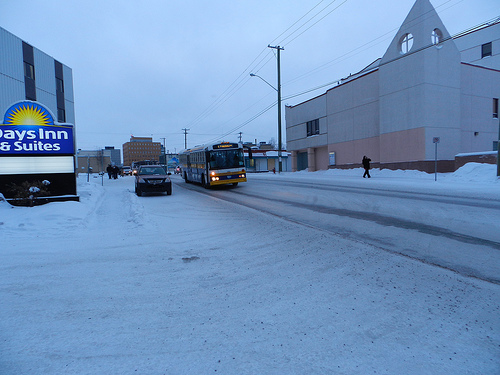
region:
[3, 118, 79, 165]
blue and yellow sign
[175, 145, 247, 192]
yellow school bus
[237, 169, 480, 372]
road is white and snow covered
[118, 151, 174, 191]
SUV next to school bus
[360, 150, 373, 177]
person is walking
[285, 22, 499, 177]
large white building near school bus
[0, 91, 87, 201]
hotel on side of road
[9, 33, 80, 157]
white hotel next to bus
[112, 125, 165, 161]
orange building in background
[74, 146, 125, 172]
tan building next to orange building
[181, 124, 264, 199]
a bus driving down a street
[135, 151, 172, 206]
a vehicle pulled off to the side of a road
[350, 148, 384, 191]
a person walking in the snow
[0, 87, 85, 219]
a hotel sign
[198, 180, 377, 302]
the road way covered in snow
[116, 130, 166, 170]
a red building with several levels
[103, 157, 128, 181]
people walking in the snow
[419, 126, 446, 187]
a metal road sign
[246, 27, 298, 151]
a wooden electrical pole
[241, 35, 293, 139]
a street lamp attached to a pole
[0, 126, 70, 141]
Days Inn writing on a sign.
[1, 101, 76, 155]
A Days Inn sign on the left.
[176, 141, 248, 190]
A bus driving down the road.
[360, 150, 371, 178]
A person in all black walking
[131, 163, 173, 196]
A maroon colored vehicle to the left of a bus.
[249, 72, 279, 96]
A light coming off a tall pole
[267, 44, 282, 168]
A tall brown electric pole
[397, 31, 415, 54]
A circular window to the left of another circular window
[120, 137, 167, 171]
A brick building straight down the street past the bus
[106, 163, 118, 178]
Group of people in dark clothes walking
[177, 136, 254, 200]
bus on snowy street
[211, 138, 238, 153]
yellow word on top of bus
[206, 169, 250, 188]
lights on front of bus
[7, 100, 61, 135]
yellow sun on sign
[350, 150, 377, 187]
person on snoy sidewalk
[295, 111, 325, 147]
window on second floor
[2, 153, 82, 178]
empty glowing white sign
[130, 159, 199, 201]
car on side of bus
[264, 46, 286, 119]
telephone pole with wires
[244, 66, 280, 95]
light on curved pole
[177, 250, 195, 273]
black mark is spotted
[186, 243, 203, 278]
black mark is spotted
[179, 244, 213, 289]
black mark is spotted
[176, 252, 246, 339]
black mark is spotted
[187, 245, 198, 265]
black mark is spotted